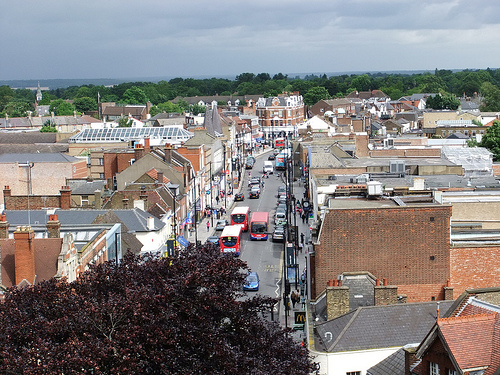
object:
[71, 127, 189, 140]
roof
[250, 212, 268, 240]
bus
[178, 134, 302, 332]
street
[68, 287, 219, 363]
tree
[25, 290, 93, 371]
purple leaves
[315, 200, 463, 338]
building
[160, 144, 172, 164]
chimney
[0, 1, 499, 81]
sky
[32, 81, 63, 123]
church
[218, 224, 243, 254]
buses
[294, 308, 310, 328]
sign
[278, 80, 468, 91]
grove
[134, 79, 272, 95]
trees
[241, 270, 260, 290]
car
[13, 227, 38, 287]
chimney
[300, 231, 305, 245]
people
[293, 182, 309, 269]
sidewalk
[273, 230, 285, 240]
cars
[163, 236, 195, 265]
letter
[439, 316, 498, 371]
roof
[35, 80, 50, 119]
steeple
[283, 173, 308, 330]
poles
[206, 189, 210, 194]
signs